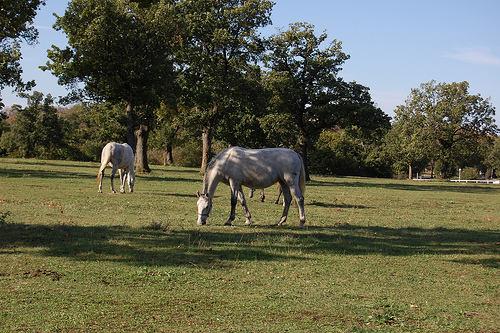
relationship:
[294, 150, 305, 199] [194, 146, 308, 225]
tail of horse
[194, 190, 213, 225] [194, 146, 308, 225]
head of horse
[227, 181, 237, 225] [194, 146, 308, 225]
leg of horse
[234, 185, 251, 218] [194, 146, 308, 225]
legs of horse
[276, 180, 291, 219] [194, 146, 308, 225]
leg of horse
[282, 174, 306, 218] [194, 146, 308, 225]
leg of horse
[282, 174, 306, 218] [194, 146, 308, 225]
leg on horse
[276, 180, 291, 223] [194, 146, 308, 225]
leg on horse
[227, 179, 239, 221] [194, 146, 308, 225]
leg on horse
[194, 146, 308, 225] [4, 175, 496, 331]
horse eating grass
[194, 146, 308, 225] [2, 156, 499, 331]
horse eating grass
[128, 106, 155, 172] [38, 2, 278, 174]
trunk on tree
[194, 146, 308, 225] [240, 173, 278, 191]
horse has belly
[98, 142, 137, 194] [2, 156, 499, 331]
horse eating grass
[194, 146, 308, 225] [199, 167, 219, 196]
horse has neck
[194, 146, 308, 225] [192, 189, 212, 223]
horse has head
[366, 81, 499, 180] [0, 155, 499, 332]
tree near pasture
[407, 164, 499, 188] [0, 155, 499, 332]
fence near pasture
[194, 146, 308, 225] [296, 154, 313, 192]
horse has tail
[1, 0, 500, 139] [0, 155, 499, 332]
sky above pasture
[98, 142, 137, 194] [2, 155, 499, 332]
horse in field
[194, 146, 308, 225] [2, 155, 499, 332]
horse in field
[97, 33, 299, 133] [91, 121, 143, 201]
trees behind horse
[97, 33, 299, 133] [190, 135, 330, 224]
trees behind horse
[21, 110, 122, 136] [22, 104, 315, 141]
leaves in trees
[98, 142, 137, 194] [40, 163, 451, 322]
horse in field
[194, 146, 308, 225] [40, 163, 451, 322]
horse in field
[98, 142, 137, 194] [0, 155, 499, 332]
horse on pasture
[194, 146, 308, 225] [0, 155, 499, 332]
horse on pasture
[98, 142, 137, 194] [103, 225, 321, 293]
horse eating grass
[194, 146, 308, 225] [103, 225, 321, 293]
horse eating grass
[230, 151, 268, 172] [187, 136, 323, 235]
reflections on horse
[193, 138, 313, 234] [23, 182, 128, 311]
horse in field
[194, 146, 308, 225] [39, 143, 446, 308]
horse in field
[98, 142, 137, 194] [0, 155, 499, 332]
horse stands in pasture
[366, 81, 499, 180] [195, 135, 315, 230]
tree behind horse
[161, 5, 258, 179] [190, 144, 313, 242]
tree behind horse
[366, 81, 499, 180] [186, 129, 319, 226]
tree behind horse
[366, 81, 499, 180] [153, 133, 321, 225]
tree behind horse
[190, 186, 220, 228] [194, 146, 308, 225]
head belongs to horse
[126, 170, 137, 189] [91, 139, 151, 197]
head belongs to horse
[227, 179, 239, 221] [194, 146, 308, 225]
leg belongs to horse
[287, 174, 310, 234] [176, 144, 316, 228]
leg belongs to horse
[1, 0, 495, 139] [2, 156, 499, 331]
sky above grass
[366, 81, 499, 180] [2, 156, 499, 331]
tree on grass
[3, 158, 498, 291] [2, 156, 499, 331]
shadows on grass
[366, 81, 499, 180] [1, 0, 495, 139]
tree under sky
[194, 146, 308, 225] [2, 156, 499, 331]
horse grazing on grass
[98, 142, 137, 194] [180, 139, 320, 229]
horse behind other horse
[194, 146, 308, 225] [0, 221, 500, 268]
horse eating in shadows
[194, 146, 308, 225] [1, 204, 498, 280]
horse by shade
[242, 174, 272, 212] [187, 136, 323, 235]
legs behind horse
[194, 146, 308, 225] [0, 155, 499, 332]
horse standing in pasture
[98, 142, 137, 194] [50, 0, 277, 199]
horse under tree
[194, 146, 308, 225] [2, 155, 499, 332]
horse grazing in field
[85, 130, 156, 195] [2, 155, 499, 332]
horse grazing in field